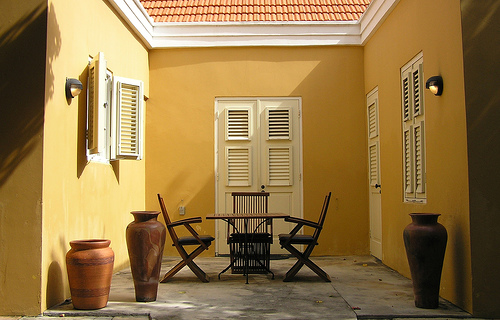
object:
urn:
[402, 212, 448, 309]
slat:
[269, 114, 289, 117]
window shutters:
[399, 49, 426, 204]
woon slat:
[119, 101, 136, 111]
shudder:
[229, 113, 251, 129]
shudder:
[268, 110, 294, 130]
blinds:
[366, 85, 382, 187]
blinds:
[218, 100, 257, 191]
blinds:
[261, 99, 294, 192]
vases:
[125, 210, 166, 302]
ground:
[416, 133, 463, 180]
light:
[66, 77, 83, 99]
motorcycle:
[144, 62, 206, 164]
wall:
[235, 118, 262, 170]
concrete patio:
[43, 254, 475, 319]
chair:
[227, 191, 274, 274]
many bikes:
[402, 212, 448, 309]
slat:
[121, 116, 136, 120]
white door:
[366, 84, 382, 262]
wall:
[363, 0, 473, 317]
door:
[214, 96, 304, 254]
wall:
[150, 47, 369, 257]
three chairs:
[157, 191, 332, 283]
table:
[205, 213, 290, 284]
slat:
[122, 92, 135, 96]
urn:
[66, 239, 115, 309]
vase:
[403, 212, 448, 308]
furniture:
[66, 191, 450, 310]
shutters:
[90, 67, 95, 150]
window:
[89, 55, 114, 164]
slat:
[121, 137, 136, 140]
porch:
[44, 255, 451, 319]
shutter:
[87, 50, 104, 154]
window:
[400, 50, 427, 205]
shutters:
[400, 49, 427, 204]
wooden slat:
[121, 108, 135, 113]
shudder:
[400, 65, 425, 125]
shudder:
[400, 127, 428, 196]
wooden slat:
[269, 132, 288, 134]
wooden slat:
[269, 150, 289, 152]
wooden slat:
[228, 160, 248, 163]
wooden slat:
[228, 132, 248, 135]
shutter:
[215, 96, 305, 255]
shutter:
[366, 85, 383, 262]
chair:
[157, 193, 216, 283]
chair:
[278, 191, 333, 281]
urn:
[125, 211, 166, 302]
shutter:
[111, 75, 144, 161]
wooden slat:
[229, 115, 248, 118]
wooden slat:
[269, 119, 289, 122]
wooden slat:
[122, 96, 137, 101]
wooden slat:
[122, 87, 136, 93]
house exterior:
[1, 1, 498, 317]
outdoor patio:
[46, 0, 486, 318]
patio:
[40, 0, 474, 317]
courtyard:
[51, 0, 479, 317]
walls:
[40, 0, 150, 314]